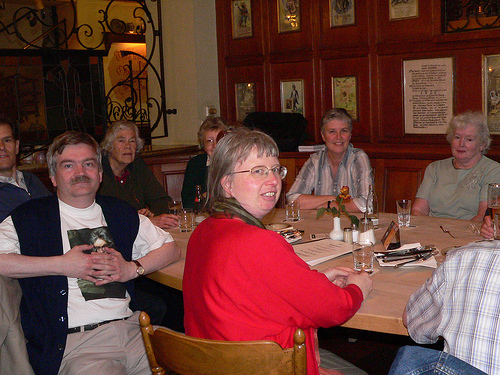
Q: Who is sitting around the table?
A: A group of people.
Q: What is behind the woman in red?
A: Back of a chair.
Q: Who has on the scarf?
A: The woman in red.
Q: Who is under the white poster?
A: The woman in the green shirt.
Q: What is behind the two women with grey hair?
A: Framed pictures on a wooden wall.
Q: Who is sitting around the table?
A: Eight people.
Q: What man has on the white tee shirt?
A: The man with the sweater vest.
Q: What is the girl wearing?
A: Jacket.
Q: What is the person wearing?
A: Shirt.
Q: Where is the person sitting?
A: Chair.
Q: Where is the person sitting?
A: Table.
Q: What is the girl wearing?
A: Sweater.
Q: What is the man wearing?
A: Vest.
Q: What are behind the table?
A: Pictures.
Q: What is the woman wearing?
A: Red shirt.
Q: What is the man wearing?
A: Vest.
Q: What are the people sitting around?
A: A table.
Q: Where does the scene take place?
A: A restaurant.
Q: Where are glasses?
A: On the table.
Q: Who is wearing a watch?
A: Man in blue vest.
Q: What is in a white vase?
A: A flower.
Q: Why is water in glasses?
A: For people to drink it.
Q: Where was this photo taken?
A: At a restaurant.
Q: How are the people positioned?
A: Seated.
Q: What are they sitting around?
A: A table.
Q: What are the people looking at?
A: The camera.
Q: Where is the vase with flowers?
A: On the table.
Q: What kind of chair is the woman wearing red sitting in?
A: Wooden chair.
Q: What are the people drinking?
A: Water.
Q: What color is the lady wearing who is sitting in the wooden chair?
A: Red.